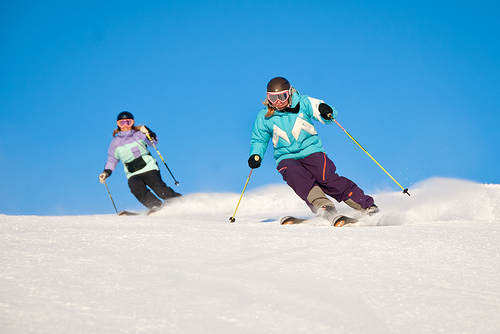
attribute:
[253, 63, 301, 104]
helmet — black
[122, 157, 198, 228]
pants — black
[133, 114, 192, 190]
pole — yellow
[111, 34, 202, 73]
sky — clear, blue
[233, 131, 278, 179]
gloves — black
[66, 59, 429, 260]
skiers — skiing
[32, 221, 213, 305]
snow — groomed, full, white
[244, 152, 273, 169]
glove — black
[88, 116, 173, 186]
jacket — purple, white, heavy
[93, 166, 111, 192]
glove — white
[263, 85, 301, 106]
goggles — pink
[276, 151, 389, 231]
trousers — purple 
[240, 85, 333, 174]
jacket — blue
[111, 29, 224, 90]
skies — blue